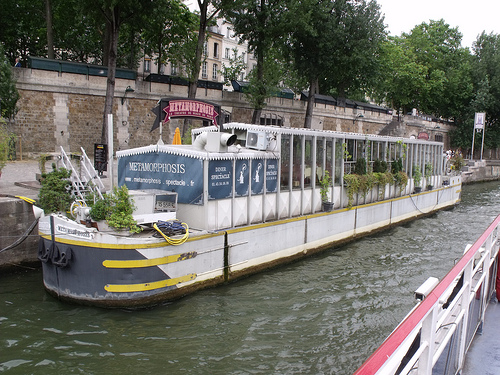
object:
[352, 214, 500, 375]
fence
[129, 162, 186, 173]
word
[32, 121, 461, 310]
structure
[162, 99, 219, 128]
sign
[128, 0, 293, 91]
building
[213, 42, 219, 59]
window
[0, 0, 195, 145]
tree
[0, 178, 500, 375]
water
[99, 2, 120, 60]
branch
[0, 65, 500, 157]
wall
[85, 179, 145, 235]
vegetation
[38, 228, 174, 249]
strip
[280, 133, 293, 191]
window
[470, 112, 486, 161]
sign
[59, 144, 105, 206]
stairs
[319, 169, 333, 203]
vegetation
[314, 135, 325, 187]
window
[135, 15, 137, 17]
leaf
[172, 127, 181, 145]
umbrella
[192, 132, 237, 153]
tube